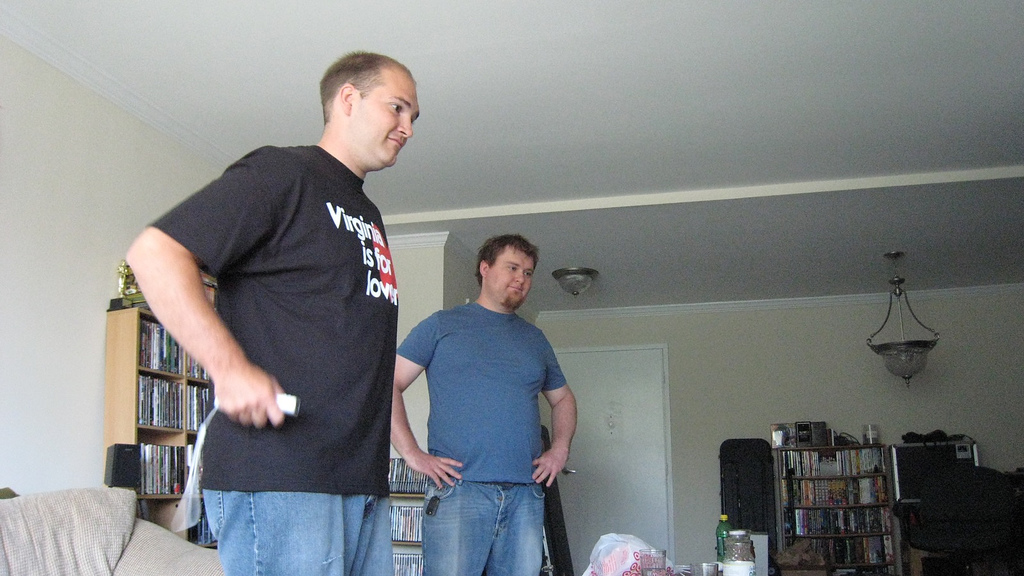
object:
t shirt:
[148, 145, 398, 494]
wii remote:
[214, 393, 301, 418]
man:
[124, 51, 422, 576]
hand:
[211, 355, 287, 429]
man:
[389, 233, 578, 575]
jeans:
[421, 477, 545, 575]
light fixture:
[866, 250, 938, 390]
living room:
[0, 0, 1024, 575]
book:
[800, 450, 819, 477]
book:
[855, 448, 869, 475]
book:
[833, 509, 849, 534]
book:
[851, 477, 871, 505]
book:
[829, 479, 848, 505]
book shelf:
[774, 444, 902, 574]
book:
[805, 450, 821, 476]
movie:
[835, 450, 841, 475]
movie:
[833, 508, 846, 534]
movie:
[794, 508, 808, 535]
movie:
[838, 509, 851, 534]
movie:
[799, 479, 812, 505]